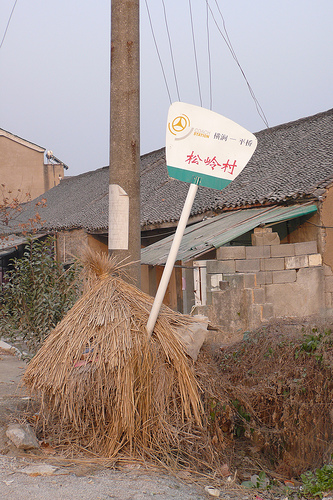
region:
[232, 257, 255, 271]
brick on the wall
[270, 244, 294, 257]
brick on the wall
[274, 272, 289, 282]
brick on the wall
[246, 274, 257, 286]
brick on the wall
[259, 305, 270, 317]
brick on the wall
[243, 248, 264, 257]
brick on the wall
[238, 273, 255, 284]
brick on the wall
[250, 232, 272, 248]
brick on the wall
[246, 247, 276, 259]
brick on the wall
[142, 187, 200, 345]
a white metal pole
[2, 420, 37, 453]
a tan rock on the ground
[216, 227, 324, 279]
a gray concrete wall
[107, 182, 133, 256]
a white paper on a pole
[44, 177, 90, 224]
a gray tin roof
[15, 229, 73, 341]
a leafy bush by a wall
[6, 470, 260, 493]
dirt and rock on the ground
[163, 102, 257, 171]
a gold and white sign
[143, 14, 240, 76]
black electric wires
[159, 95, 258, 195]
the sign is white.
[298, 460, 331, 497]
the weeds are green.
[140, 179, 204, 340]
the pole is white.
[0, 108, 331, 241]
the roof is grey.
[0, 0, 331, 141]
the sky is blue.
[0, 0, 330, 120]
the sky is clear.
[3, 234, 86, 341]
the bushes are green.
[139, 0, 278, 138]
the wires are black.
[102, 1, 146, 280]
the pole is brown.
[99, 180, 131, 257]
white paper on the pole.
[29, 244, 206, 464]
haystack beside the road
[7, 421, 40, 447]
a rock by the haystack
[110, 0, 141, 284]
telephone pole by the haystack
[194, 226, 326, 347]
cinder blocks on the wall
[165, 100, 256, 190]
a green, white, yellow, blue and red sign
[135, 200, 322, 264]
a make-shift tin roof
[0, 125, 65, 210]
a substantial building on the left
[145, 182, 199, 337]
a white post in the haystack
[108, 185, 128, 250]
a sign on the post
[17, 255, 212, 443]
straw stacked on the ground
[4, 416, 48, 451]
rock piled next to the straw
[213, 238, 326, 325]
wall made of bricks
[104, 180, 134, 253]
paper on a wooden post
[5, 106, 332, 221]
grey roof on a house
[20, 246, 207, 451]
hay at the bottom of a post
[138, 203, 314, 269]
green awning on a house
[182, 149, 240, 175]
red characters on a sign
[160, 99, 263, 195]
white sign on a pole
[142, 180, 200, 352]
white pole holding a sign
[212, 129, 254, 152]
grey characters on a sign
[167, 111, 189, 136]
yellow symbol on a sign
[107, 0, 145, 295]
tall brown wooden post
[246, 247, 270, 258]
brick is brown and gray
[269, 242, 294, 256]
brick is brown and gray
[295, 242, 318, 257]
brick is brown and gray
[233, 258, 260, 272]
brick is brown and gray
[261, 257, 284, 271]
brick is brown and gray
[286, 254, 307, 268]
brick is brown and gray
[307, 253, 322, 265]
brick is brown and gray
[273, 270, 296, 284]
brick is brown and gray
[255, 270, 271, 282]
brick is brown and gray